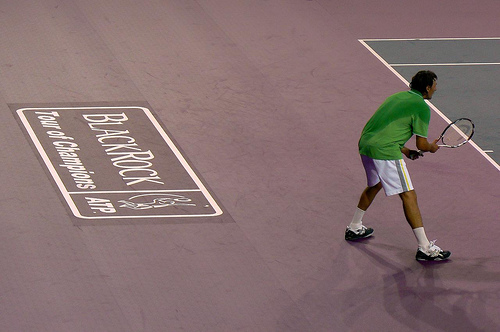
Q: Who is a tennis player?
A: A male.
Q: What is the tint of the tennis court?
A: Green.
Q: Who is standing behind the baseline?
A: A tennis player.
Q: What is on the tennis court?
A: A white logo.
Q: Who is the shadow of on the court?
A: A tennis player.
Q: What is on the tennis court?
A: A white baseline.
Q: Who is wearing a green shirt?
A: A tennis player.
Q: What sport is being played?
A: Tennis.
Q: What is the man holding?
A: Tennis racket.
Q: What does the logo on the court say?
A: BlackRock.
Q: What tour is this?
A: ATP.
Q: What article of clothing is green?
A: Shirt.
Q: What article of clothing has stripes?
A: Shorts.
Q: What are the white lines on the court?
A: Boundary lines.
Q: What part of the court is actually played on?
A: The green part.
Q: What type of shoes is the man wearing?
A: Tennis shoes.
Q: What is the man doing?
A: Playing tennis.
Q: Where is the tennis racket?
A: In the hands.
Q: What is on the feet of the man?
A: Sneakers.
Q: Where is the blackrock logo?
A: On the ground.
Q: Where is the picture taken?
A: Tennis tournament.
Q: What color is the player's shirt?
A: Green.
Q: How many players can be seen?
A: One.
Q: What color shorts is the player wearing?
A: White.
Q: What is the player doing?
A: Waiting for a ball to be served.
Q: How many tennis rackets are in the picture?
A: One.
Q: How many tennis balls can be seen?
A: None.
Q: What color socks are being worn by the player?
A: White.